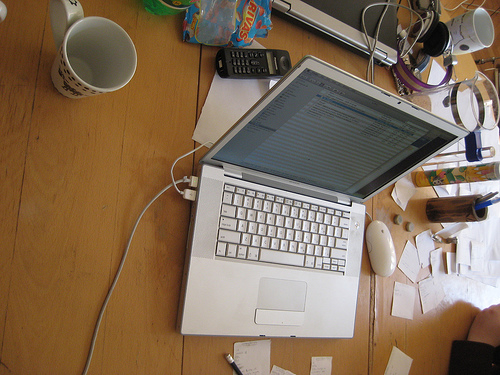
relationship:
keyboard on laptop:
[214, 184, 353, 282] [174, 56, 471, 340]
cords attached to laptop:
[86, 139, 201, 372] [174, 56, 471, 340]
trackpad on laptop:
[247, 274, 314, 312] [136, 49, 471, 349]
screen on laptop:
[198, 56, 478, 197] [174, 56, 471, 340]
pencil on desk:
[215, 350, 251, 372] [35, 27, 462, 357]